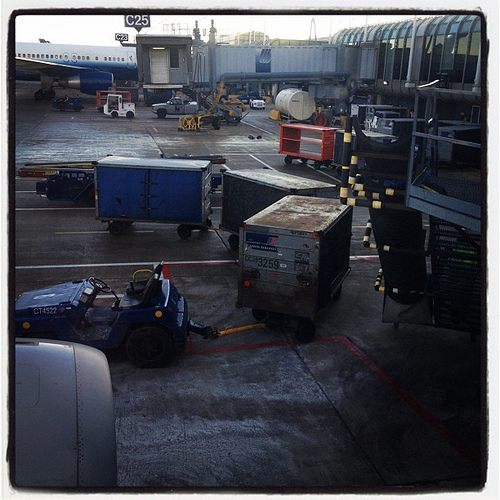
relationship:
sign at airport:
[123, 15, 153, 32] [14, 16, 484, 489]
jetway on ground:
[88, 30, 322, 93] [10, 87, 500, 500]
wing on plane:
[15, 56, 100, 71] [15, 42, 138, 102]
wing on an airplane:
[11, 52, 106, 71] [18, 38, 138, 92]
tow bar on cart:
[218, 320, 271, 340] [16, 257, 216, 367]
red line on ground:
[341, 326, 434, 433] [157, 359, 377, 494]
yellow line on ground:
[56, 224, 98, 237] [161, 375, 329, 457]